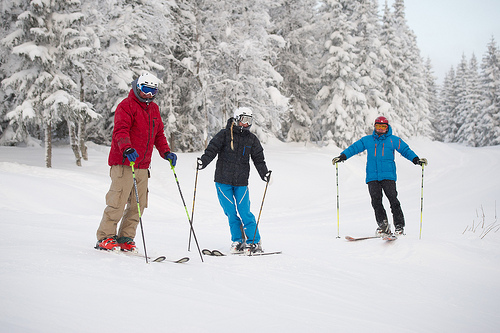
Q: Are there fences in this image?
A: No, there are no fences.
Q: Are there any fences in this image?
A: No, there are no fences.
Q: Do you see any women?
A: Yes, there is a woman.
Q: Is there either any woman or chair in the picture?
A: Yes, there is a woman.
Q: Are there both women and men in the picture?
A: Yes, there are both a woman and a man.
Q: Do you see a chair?
A: No, there are no chairs.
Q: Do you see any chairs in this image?
A: No, there are no chairs.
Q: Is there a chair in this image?
A: No, there are no chairs.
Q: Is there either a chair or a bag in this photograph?
A: No, there are no chairs or bags.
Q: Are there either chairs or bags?
A: No, there are no chairs or bags.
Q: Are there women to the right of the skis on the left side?
A: Yes, there is a woman to the right of the skis.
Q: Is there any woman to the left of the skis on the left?
A: No, the woman is to the right of the skis.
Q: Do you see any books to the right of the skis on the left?
A: No, there is a woman to the right of the skis.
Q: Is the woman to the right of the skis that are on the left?
A: Yes, the woman is to the right of the skis.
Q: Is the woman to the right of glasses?
A: No, the woman is to the right of the skis.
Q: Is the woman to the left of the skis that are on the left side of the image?
A: No, the woman is to the right of the skis.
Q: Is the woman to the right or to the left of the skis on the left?
A: The woman is to the right of the skis.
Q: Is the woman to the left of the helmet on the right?
A: Yes, the woman is to the left of the helmet.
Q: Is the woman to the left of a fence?
A: No, the woman is to the left of the helmet.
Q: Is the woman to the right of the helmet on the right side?
A: No, the woman is to the left of the helmet.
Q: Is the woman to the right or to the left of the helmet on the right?
A: The woman is to the left of the helmet.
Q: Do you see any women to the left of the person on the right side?
A: Yes, there is a woman to the left of the person.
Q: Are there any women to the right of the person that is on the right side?
A: No, the woman is to the left of the person.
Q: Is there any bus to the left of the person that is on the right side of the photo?
A: No, there is a woman to the left of the person.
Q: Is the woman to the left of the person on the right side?
A: Yes, the woman is to the left of the person.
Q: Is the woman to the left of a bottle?
A: No, the woman is to the left of the person.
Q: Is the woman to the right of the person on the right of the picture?
A: No, the woman is to the left of the person.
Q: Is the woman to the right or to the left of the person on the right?
A: The woman is to the left of the person.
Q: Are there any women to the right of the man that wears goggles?
A: Yes, there is a woman to the right of the man.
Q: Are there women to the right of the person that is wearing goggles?
A: Yes, there is a woman to the right of the man.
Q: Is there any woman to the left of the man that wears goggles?
A: No, the woman is to the right of the man.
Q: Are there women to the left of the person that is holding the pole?
A: No, the woman is to the right of the man.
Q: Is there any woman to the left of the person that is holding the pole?
A: No, the woman is to the right of the man.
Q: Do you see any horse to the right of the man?
A: No, there is a woman to the right of the man.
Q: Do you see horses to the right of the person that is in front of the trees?
A: No, there is a woman to the right of the man.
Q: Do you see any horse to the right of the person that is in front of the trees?
A: No, there is a woman to the right of the man.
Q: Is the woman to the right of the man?
A: Yes, the woman is to the right of the man.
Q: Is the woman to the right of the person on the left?
A: Yes, the woman is to the right of the man.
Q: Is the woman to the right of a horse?
A: No, the woman is to the right of the man.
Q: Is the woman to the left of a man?
A: No, the woman is to the right of a man.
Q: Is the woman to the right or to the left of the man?
A: The woman is to the right of the man.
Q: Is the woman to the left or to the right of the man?
A: The woman is to the right of the man.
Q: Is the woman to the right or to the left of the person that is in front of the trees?
A: The woman is to the right of the man.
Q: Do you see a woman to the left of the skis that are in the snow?
A: Yes, there is a woman to the left of the skis.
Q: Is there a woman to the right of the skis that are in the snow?
A: No, the woman is to the left of the skis.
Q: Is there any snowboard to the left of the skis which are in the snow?
A: No, there is a woman to the left of the skis.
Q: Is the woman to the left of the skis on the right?
A: Yes, the woman is to the left of the skis.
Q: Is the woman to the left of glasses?
A: No, the woman is to the left of the skis.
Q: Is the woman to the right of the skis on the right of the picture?
A: No, the woman is to the left of the skis.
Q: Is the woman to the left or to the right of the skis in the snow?
A: The woman is to the left of the skis.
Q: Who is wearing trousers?
A: The woman is wearing trousers.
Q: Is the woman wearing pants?
A: Yes, the woman is wearing pants.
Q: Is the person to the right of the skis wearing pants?
A: Yes, the woman is wearing pants.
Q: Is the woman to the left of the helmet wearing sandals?
A: No, the woman is wearing pants.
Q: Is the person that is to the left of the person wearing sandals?
A: No, the woman is wearing pants.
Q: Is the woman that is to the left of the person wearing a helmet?
A: Yes, the woman is wearing a helmet.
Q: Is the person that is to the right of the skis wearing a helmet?
A: Yes, the woman is wearing a helmet.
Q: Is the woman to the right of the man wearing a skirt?
A: No, the woman is wearing a helmet.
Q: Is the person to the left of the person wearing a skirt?
A: No, the woman is wearing a helmet.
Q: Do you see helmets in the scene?
A: Yes, there is a helmet.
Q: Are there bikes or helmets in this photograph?
A: Yes, there is a helmet.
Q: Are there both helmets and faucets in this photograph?
A: No, there is a helmet but no faucets.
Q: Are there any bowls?
A: No, there are no bowls.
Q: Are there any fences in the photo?
A: No, there are no fences.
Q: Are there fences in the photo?
A: No, there are no fences.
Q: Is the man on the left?
A: Yes, the man is on the left of the image.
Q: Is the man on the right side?
A: No, the man is on the left of the image.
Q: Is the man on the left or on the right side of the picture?
A: The man is on the left of the image.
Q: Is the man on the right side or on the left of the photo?
A: The man is on the left of the image.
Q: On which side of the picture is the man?
A: The man is on the left of the image.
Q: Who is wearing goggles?
A: The man is wearing goggles.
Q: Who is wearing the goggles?
A: The man is wearing goggles.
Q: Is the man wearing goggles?
A: Yes, the man is wearing goggles.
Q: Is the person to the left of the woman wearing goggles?
A: Yes, the man is wearing goggles.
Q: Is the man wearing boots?
A: No, the man is wearing goggles.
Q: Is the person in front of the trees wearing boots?
A: No, the man is wearing goggles.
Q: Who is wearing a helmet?
A: The man is wearing a helmet.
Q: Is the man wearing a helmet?
A: Yes, the man is wearing a helmet.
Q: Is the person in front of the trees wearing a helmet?
A: Yes, the man is wearing a helmet.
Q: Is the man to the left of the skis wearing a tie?
A: No, the man is wearing a helmet.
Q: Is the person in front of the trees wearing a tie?
A: No, the man is wearing a helmet.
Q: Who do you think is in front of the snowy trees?
A: The man is in front of the trees.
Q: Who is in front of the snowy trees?
A: The man is in front of the trees.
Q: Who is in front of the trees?
A: The man is in front of the trees.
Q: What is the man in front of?
A: The man is in front of the trees.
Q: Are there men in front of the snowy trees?
A: Yes, there is a man in front of the trees.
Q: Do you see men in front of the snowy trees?
A: Yes, there is a man in front of the trees.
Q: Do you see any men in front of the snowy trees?
A: Yes, there is a man in front of the trees.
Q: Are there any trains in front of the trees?
A: No, there is a man in front of the trees.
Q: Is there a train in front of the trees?
A: No, there is a man in front of the trees.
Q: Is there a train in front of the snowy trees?
A: No, there is a man in front of the trees.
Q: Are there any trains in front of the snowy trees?
A: No, there is a man in front of the trees.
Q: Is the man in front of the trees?
A: Yes, the man is in front of the trees.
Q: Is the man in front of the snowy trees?
A: Yes, the man is in front of the trees.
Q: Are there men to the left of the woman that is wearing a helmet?
A: Yes, there is a man to the left of the woman.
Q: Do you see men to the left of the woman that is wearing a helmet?
A: Yes, there is a man to the left of the woman.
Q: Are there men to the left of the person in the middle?
A: Yes, there is a man to the left of the woman.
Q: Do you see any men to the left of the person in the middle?
A: Yes, there is a man to the left of the woman.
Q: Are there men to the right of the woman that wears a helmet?
A: No, the man is to the left of the woman.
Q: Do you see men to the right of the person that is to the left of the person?
A: No, the man is to the left of the woman.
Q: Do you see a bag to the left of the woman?
A: No, there is a man to the left of the woman.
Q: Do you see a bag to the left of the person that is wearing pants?
A: No, there is a man to the left of the woman.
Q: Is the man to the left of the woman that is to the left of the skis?
A: Yes, the man is to the left of the woman.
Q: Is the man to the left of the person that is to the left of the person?
A: Yes, the man is to the left of the woman.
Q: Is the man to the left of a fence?
A: No, the man is to the left of the woman.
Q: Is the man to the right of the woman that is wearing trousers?
A: No, the man is to the left of the woman.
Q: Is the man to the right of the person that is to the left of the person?
A: No, the man is to the left of the woman.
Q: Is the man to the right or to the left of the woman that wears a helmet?
A: The man is to the left of the woman.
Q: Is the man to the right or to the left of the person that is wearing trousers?
A: The man is to the left of the woman.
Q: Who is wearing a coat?
A: The man is wearing a coat.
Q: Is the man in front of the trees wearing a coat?
A: Yes, the man is wearing a coat.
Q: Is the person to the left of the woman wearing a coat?
A: Yes, the man is wearing a coat.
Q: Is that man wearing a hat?
A: No, the man is wearing a coat.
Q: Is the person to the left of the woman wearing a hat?
A: No, the man is wearing a coat.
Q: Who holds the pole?
A: The man holds the pole.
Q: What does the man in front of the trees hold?
A: The man holds the pole.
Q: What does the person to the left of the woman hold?
A: The man holds the pole.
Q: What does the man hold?
A: The man holds the pole.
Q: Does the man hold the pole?
A: Yes, the man holds the pole.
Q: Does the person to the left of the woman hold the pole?
A: Yes, the man holds the pole.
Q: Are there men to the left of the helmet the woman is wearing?
A: Yes, there is a man to the left of the helmet.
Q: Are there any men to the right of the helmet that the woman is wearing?
A: No, the man is to the left of the helmet.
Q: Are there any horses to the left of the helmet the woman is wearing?
A: No, there is a man to the left of the helmet.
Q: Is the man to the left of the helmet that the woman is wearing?
A: Yes, the man is to the left of the helmet.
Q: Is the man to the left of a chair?
A: No, the man is to the left of the helmet.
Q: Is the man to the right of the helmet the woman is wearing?
A: No, the man is to the left of the helmet.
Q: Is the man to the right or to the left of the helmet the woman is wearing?
A: The man is to the left of the helmet.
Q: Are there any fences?
A: No, there are no fences.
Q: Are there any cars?
A: No, there are no cars.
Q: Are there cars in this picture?
A: No, there are no cars.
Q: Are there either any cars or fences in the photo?
A: No, there are no cars or fences.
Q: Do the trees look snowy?
A: Yes, the trees are snowy.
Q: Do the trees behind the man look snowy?
A: Yes, the trees are snowy.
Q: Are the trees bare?
A: No, the trees are snowy.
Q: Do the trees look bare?
A: No, the trees are snowy.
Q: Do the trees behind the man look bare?
A: No, the trees are snowy.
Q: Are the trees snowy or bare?
A: The trees are snowy.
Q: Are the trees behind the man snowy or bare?
A: The trees are snowy.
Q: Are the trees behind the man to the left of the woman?
A: Yes, the trees are behind the man.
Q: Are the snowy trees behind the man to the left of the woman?
A: Yes, the trees are behind the man.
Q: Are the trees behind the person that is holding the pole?
A: Yes, the trees are behind the man.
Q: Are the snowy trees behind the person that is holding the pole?
A: Yes, the trees are behind the man.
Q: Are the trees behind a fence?
A: No, the trees are behind the man.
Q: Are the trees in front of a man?
A: No, the trees are behind a man.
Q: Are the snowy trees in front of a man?
A: No, the trees are behind a man.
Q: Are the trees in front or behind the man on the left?
A: The trees are behind the man.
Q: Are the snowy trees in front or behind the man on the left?
A: The trees are behind the man.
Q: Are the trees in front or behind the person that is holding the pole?
A: The trees are behind the man.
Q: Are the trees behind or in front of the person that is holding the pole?
A: The trees are behind the man.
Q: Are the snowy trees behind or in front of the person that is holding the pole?
A: The trees are behind the man.